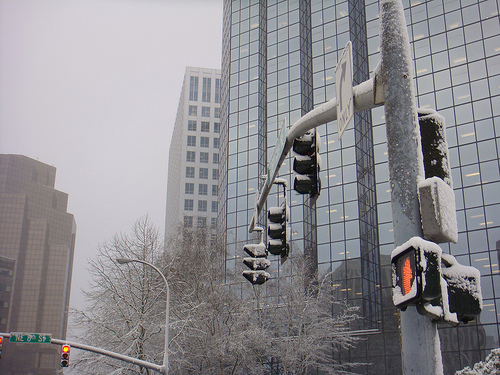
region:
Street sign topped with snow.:
[3, 323, 54, 351]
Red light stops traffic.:
[53, 335, 85, 365]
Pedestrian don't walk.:
[385, 238, 435, 306]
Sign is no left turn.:
[321, 44, 364, 136]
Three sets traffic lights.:
[244, 124, 325, 283]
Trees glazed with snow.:
[100, 216, 231, 373]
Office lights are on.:
[458, 6, 493, 242]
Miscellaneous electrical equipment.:
[417, 102, 482, 328]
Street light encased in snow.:
[106, 252, 192, 369]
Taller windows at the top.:
[160, 58, 226, 178]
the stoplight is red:
[55, 338, 75, 372]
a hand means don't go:
[389, 249, 420, 297]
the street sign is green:
[8, 329, 52, 345]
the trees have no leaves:
[104, 232, 314, 370]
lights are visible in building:
[444, 18, 494, 224]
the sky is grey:
[45, 96, 157, 223]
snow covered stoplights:
[243, 202, 292, 287]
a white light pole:
[115, 251, 176, 368]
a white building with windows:
[152, 92, 219, 241]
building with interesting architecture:
[7, 156, 83, 337]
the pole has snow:
[240, 0, 481, 374]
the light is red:
[60, 341, 70, 368]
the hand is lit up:
[398, 255, 415, 297]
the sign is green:
[8, 330, 52, 345]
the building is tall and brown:
[0, 153, 80, 373]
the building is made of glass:
[218, 0, 498, 373]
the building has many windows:
[165, 66, 218, 248]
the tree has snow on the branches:
[68, 215, 365, 372]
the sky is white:
[0, 0, 220, 349]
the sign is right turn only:
[331, 43, 354, 137]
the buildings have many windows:
[157, 1, 494, 373]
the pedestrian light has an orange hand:
[385, 231, 445, 324]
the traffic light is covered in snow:
[224, 118, 334, 295]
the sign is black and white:
[316, 26, 378, 161]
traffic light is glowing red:
[0, 317, 82, 373]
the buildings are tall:
[152, 1, 499, 373]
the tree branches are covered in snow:
[67, 218, 388, 367]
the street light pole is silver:
[97, 244, 217, 374]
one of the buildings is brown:
[0, 145, 100, 374]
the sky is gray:
[1, 0, 226, 374]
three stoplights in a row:
[226, 126, 326, 291]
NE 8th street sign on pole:
[7, 325, 72, 347]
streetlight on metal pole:
[105, 242, 175, 373]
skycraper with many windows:
[179, 57, 239, 263]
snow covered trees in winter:
[156, 232, 369, 371]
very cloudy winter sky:
[43, 25, 155, 169]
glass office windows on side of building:
[229, 0, 264, 189]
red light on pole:
[62, 338, 84, 367]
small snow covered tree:
[454, 341, 498, 373]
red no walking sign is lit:
[392, 249, 445, 305]